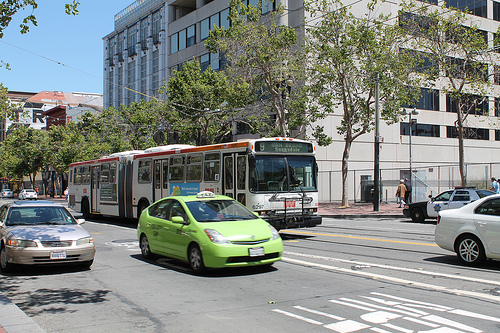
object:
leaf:
[193, 83, 201, 92]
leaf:
[12, 145, 28, 149]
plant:
[391, 0, 499, 189]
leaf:
[76, 132, 89, 136]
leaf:
[187, 88, 192, 95]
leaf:
[17, 134, 26, 141]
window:
[492, 0, 500, 21]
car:
[433, 193, 500, 267]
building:
[167, 0, 500, 204]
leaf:
[87, 135, 101, 140]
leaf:
[82, 147, 93, 156]